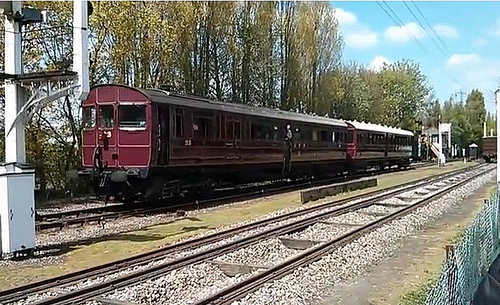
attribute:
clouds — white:
[333, 9, 495, 117]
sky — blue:
[0, 0, 497, 132]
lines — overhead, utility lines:
[380, 0, 495, 101]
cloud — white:
[328, 7, 365, 26]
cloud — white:
[339, 26, 380, 51]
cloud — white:
[380, 17, 461, 44]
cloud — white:
[367, 55, 392, 71]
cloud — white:
[447, 50, 499, 92]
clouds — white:
[440, 50, 498, 96]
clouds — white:
[332, 5, 427, 67]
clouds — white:
[437, 9, 497, 60]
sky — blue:
[317, 5, 495, 102]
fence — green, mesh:
[432, 193, 497, 304]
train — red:
[43, 44, 445, 196]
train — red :
[81, 59, 428, 197]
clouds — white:
[363, 27, 393, 48]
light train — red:
[1, 5, 106, 170]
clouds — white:
[323, 7, 474, 77]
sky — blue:
[332, 10, 482, 75]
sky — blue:
[375, 3, 497, 52]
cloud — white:
[445, 53, 485, 73]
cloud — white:
[471, 27, 498, 53]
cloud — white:
[306, 5, 358, 30]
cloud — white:
[365, 52, 393, 75]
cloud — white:
[384, 21, 424, 43]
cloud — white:
[429, 23, 459, 41]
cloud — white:
[318, 7, 356, 27]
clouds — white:
[322, 15, 458, 53]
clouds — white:
[4, 5, 499, 120]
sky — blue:
[0, 0, 497, 149]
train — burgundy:
[46, 67, 439, 243]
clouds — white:
[332, 5, 454, 53]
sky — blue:
[337, 0, 497, 80]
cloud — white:
[435, 50, 485, 71]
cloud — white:
[431, 19, 461, 41]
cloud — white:
[380, 19, 424, 44]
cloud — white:
[330, 6, 378, 51]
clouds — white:
[339, 20, 410, 51]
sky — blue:
[419, 6, 477, 65]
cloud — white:
[323, 5, 375, 51]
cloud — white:
[470, 17, 499, 42]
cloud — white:
[443, 53, 498, 95]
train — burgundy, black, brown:
[73, 83, 413, 203]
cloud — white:
[322, 6, 355, 28]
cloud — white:
[380, 21, 428, 48]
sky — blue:
[5, 0, 494, 110]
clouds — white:
[366, 13, 493, 80]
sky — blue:
[334, 11, 459, 75]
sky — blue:
[327, 4, 495, 77]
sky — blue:
[339, 3, 488, 62]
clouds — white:
[387, 20, 463, 48]